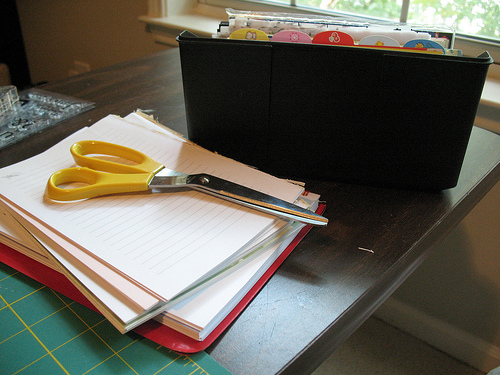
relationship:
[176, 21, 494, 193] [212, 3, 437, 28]
box full of craft ideas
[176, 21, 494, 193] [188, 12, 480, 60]
box in dividers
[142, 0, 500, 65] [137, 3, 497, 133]
window of a window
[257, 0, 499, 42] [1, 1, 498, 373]
window of a room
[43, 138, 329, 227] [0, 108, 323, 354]
scissor blades on a book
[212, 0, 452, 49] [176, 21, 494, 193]
papers by a box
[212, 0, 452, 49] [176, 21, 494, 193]
papers in a box